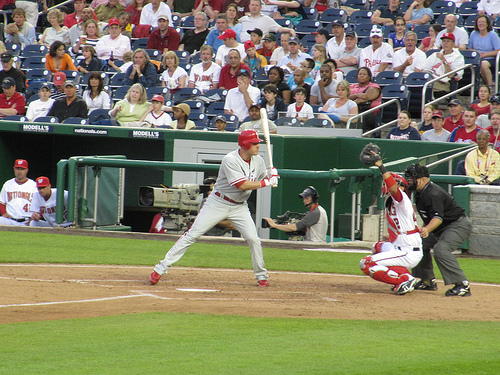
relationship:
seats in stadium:
[288, 7, 373, 42] [3, 0, 484, 372]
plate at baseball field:
[173, 280, 224, 296] [0, 253, 334, 329]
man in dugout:
[0, 159, 37, 226] [9, 129, 229, 249]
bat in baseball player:
[251, 99, 279, 174] [148, 121, 281, 288]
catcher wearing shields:
[359, 142, 424, 295] [357, 235, 387, 275]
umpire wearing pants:
[403, 161, 471, 297] [413, 213, 483, 294]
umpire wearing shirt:
[403, 161, 471, 297] [404, 180, 463, 234]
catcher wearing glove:
[359, 142, 424, 295] [354, 139, 393, 175]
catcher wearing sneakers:
[344, 158, 434, 245] [391, 272, 420, 296]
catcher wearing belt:
[359, 142, 424, 295] [391, 240, 431, 259]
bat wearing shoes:
[259, 107, 274, 169] [148, 271, 162, 285]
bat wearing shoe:
[259, 107, 274, 169] [257, 280, 269, 287]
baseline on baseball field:
[0, 294, 108, 309] [55, 250, 302, 329]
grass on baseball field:
[175, 303, 300, 368] [0, 253, 334, 329]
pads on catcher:
[368, 268, 395, 287] [369, 156, 426, 226]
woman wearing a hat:
[164, 92, 209, 132] [170, 95, 197, 116]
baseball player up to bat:
[215, 123, 278, 174] [251, 98, 286, 175]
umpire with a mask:
[403, 161, 471, 297] [401, 164, 423, 201]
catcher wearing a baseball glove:
[359, 142, 424, 295] [350, 136, 388, 185]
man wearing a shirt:
[462, 125, 499, 163] [466, 150, 493, 185]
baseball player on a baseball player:
[148, 121, 281, 288] [148, 121, 281, 288]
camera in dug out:
[138, 181, 306, 238] [2, 122, 468, 243]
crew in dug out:
[205, 184, 327, 240] [2, 122, 468, 243]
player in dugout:
[28, 177, 69, 226] [3, 123, 466, 241]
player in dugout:
[0, 157, 42, 224] [3, 123, 466, 241]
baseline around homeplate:
[2, 275, 368, 315] [174, 283, 222, 293]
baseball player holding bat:
[148, 121, 281, 288] [255, 107, 277, 186]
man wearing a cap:
[0, 159, 42, 226] [14, 157, 25, 169]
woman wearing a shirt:
[463, 130, 498, 182] [462, 148, 499, 180]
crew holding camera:
[262, 185, 328, 242] [261, 211, 304, 232]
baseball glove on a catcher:
[357, 141, 382, 165] [359, 142, 424, 295]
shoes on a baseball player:
[148, 268, 269, 282] [148, 121, 281, 288]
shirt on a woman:
[44, 54, 74, 68] [44, 41, 77, 81]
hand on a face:
[316, 76, 329, 86] [321, 66, 329, 80]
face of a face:
[321, 66, 329, 80] [310, 63, 339, 105]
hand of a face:
[316, 76, 329, 86] [310, 63, 339, 105]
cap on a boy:
[212, 113, 225, 123] [212, 114, 232, 131]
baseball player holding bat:
[148, 121, 281, 288] [259, 108, 279, 188]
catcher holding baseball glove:
[359, 142, 424, 295] [357, 141, 382, 165]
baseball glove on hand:
[357, 141, 382, 165] [369, 150, 383, 167]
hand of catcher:
[369, 150, 383, 167] [359, 142, 424, 295]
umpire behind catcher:
[401, 160, 472, 296] [359, 142, 424, 295]